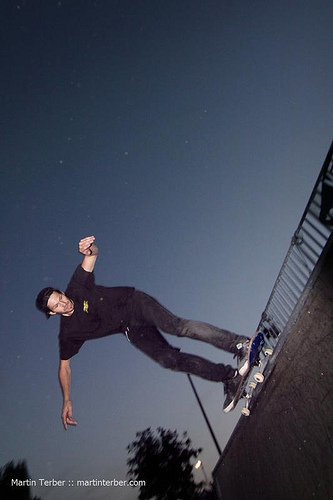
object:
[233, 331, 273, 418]
deck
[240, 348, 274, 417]
wheels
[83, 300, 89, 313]
logo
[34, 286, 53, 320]
hat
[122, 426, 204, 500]
black tree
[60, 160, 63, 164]
star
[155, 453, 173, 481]
leaves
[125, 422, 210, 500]
tree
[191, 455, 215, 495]
lightpost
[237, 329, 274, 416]
skateboard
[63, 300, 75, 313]
beard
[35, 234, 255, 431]
man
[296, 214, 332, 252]
metal fence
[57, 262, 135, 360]
shirt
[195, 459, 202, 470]
light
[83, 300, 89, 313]
mark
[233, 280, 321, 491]
ramp